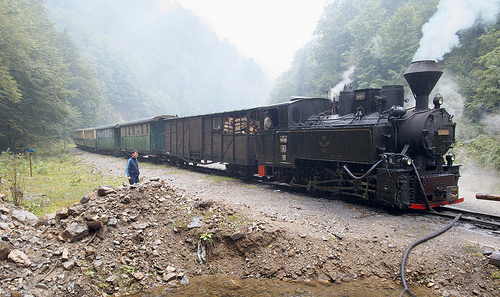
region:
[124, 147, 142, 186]
a man in a blue jacket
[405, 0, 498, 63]
steam comming from engine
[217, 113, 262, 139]
logs in train car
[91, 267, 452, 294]
a small pool of water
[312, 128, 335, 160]
gold logo on side of engine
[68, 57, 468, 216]
a train with 3 boxcars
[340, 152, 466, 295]
a black water hose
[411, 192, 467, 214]
red bumper on engine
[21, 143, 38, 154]
blue tarp under trees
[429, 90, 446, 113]
light on front of engine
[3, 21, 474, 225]
Train pulled by old fashioned locomotive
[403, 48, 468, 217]
The front of a historic train engine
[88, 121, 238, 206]
A man next to railroad tracks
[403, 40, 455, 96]
The chimney on an old fashioned train engine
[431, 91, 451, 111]
Light mounted on a historic train engine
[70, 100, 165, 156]
Yellow and green passenger train cars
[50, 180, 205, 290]
A pile of dirt and gravel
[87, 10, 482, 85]
Air pollution caused by a train engine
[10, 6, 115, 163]
Trees near a railroad track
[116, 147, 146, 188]
A man in a blue jacket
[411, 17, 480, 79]
smoke coming from train's smoke stack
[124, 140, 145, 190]
man standing near dirt pile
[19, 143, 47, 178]
small wood pole in grass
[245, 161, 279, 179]
red marking on train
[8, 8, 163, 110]
forest of green trees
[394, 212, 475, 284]
black hose coming from train tracks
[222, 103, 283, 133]
lumber stacked in train car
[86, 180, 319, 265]
tall mound of dirt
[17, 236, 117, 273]
pebbles in dirt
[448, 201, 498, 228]
black train tracks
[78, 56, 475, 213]
Train moving on tracks.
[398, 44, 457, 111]
A train's smoke stack.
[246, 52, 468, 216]
A train's engine.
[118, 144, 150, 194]
Man standing near train.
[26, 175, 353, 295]
Dirt piled next to train track.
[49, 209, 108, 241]
Rocks in dirt pile.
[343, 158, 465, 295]
Hose leading from train.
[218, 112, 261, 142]
Wood stacked inside train.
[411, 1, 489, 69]
Smoke from smoke stack.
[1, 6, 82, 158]
Trees next to train track.